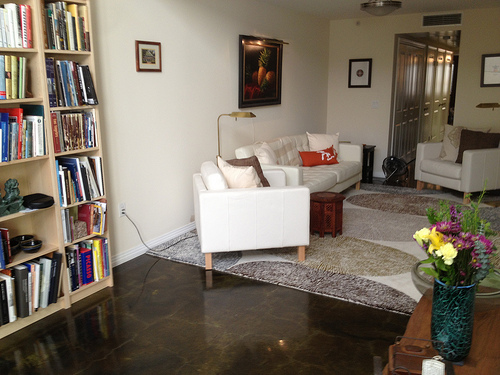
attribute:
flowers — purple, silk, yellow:
[409, 219, 494, 286]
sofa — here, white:
[234, 136, 362, 198]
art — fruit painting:
[237, 33, 284, 109]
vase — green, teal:
[431, 276, 476, 364]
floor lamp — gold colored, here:
[217, 111, 253, 157]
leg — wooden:
[203, 253, 214, 272]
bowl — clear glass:
[411, 257, 499, 314]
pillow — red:
[299, 149, 335, 166]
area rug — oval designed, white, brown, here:
[148, 182, 499, 315]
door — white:
[394, 44, 415, 166]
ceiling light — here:
[359, 1, 401, 18]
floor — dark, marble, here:
[3, 255, 411, 374]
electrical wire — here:
[124, 213, 197, 252]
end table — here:
[310, 191, 344, 237]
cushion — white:
[198, 161, 225, 190]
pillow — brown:
[455, 131, 497, 165]